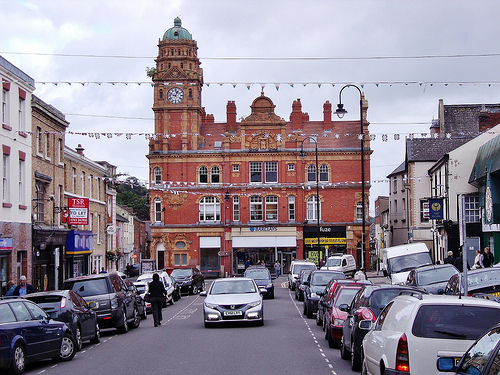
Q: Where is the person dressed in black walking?
A: On the road.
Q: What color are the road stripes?
A: White.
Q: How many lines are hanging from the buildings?
A: Seven.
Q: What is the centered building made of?
A: Brick.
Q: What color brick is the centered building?
A: Red.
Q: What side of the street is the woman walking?
A: The Left.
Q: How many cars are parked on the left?
A: Six.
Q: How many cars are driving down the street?
A: Two.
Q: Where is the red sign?
A: The left side of the street.